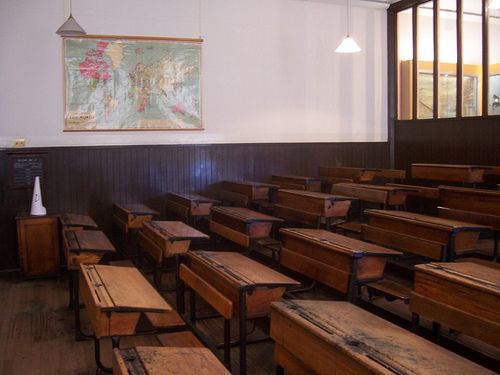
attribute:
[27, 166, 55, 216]
cone — white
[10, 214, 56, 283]
table — wooden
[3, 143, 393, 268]
paneling — wooden 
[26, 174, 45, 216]
cap — white 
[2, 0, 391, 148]
wall — white 